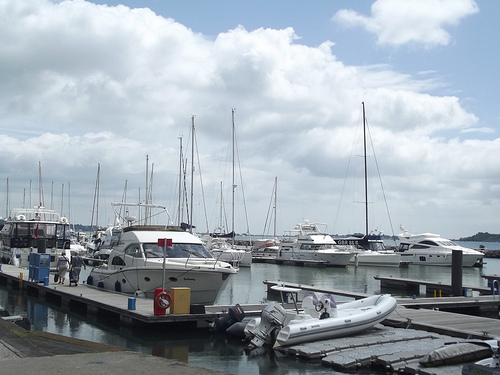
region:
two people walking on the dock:
[50, 248, 92, 288]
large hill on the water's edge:
[448, 226, 498, 242]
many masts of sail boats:
[0, 100, 397, 235]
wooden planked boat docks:
[261, 261, 498, 338]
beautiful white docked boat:
[88, 204, 240, 306]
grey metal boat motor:
[230, 299, 287, 364]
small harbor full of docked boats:
[0, 214, 499, 373]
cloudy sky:
[1, 0, 498, 227]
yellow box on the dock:
[165, 285, 199, 316]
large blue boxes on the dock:
[25, 248, 53, 288]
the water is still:
[288, 266, 337, 284]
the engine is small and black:
[209, 301, 245, 338]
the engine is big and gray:
[238, 296, 287, 356]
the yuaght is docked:
[96, 189, 237, 294]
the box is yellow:
[168, 286, 192, 316]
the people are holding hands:
[58, 249, 89, 288]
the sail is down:
[258, 172, 282, 235]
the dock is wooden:
[415, 309, 450, 328]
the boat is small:
[242, 294, 409, 339]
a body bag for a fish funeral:
[414, 327, 494, 373]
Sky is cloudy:
[5, 7, 497, 248]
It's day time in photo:
[18, 12, 483, 227]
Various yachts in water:
[0, 135, 471, 362]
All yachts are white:
[17, 159, 488, 343]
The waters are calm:
[17, 179, 442, 357]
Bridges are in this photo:
[12, 235, 492, 373]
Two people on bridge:
[50, 236, 110, 298]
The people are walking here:
[47, 233, 87, 287]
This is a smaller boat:
[198, 279, 405, 357]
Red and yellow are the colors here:
[127, 215, 217, 327]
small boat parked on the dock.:
[213, 285, 401, 351]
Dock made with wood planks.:
[410, 305, 499, 339]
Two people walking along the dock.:
[50, 247, 90, 287]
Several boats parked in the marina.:
[6, 71, 491, 361]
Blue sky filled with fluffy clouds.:
[12, 4, 493, 166]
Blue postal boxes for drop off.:
[24, 247, 56, 287]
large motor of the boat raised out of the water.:
[246, 296, 290, 359]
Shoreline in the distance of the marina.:
[449, 219, 499, 254]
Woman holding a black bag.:
[54, 250, 73, 284]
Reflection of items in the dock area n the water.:
[18, 287, 96, 338]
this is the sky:
[247, 5, 300, 20]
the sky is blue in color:
[240, 5, 296, 15]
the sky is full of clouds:
[3, 6, 487, 205]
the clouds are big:
[99, 2, 281, 189]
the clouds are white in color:
[165, 71, 308, 106]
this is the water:
[265, 264, 286, 277]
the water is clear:
[291, 269, 340, 284]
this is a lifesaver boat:
[243, 287, 397, 335]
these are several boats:
[43, 202, 491, 285]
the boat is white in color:
[140, 230, 155, 241]